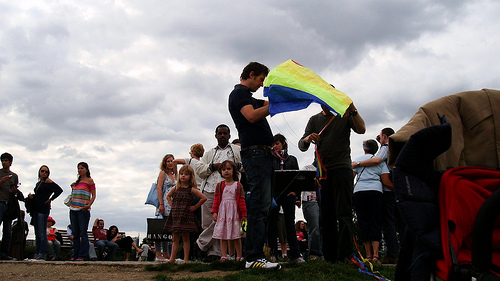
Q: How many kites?
A: One.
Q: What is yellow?
A: Kite.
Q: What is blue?
A: Sky.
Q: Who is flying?
A: Man.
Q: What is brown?
A: Ground.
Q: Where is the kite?
A: In the man's hand.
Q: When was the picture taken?
A: Daytime.